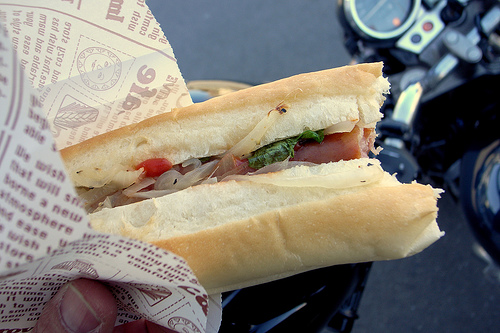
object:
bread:
[58, 61, 449, 298]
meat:
[228, 126, 382, 176]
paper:
[0, 1, 223, 333]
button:
[422, 21, 435, 33]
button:
[411, 34, 421, 43]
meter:
[336, 0, 434, 53]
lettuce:
[248, 128, 326, 169]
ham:
[235, 126, 383, 175]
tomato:
[136, 158, 173, 178]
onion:
[81, 156, 217, 205]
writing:
[0, 145, 75, 256]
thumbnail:
[57, 281, 102, 332]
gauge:
[353, 0, 417, 34]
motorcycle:
[331, 0, 498, 286]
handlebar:
[376, 71, 427, 179]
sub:
[45, 61, 450, 275]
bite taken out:
[344, 60, 445, 259]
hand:
[32, 279, 122, 332]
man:
[29, 277, 118, 332]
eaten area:
[357, 59, 446, 241]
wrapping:
[0, 4, 225, 333]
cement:
[139, 3, 499, 328]